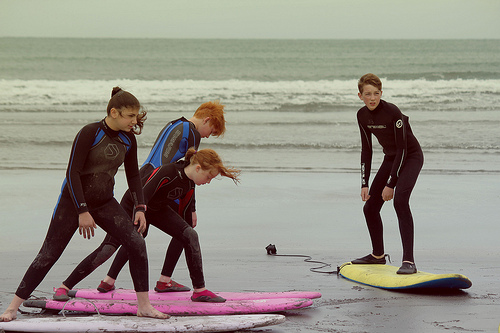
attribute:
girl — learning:
[1, 82, 173, 325]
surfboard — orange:
[22, 297, 312, 310]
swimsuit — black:
[353, 92, 425, 264]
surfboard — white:
[1, 315, 284, 331]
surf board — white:
[92, 277, 387, 301]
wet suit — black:
[351, 96, 427, 266]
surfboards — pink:
[64, 264, 321, 325]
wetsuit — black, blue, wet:
[16, 117, 149, 299]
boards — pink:
[38, 273, 338, 316]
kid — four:
[352, 69, 424, 275]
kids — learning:
[1, 3, 444, 332]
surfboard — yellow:
[338, 258, 470, 295]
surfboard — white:
[255, 283, 375, 311]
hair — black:
[81, 86, 153, 106]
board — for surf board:
[345, 250, 480, 313]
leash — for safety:
[258, 230, 340, 289]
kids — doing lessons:
[3, 73, 471, 331]